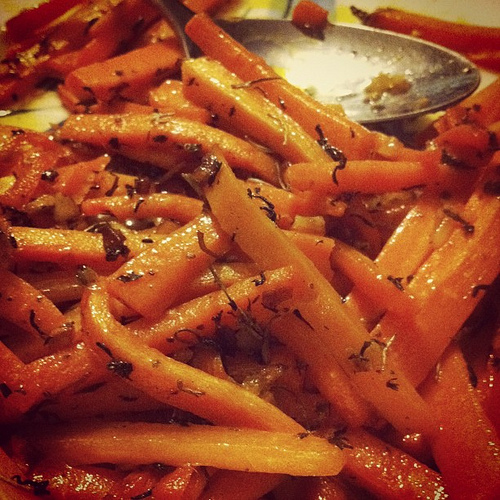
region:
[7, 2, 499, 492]
Cooked range vegetables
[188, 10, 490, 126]
Empty metal dish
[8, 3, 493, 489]
Oily cooked vegetables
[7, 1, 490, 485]
Vegetables cut in large pieces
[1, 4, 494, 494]
Vegetables covered with herbs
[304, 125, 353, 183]
Herb covering vegetables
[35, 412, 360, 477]
Rectangular vegetable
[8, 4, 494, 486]
Orange vegetables seasoned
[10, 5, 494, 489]
Vegetables with covered with some herbs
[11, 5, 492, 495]
Vegetables net to empty dish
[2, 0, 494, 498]
dish of sliced, buttered, herb carrots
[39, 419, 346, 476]
carrot with almost no herbs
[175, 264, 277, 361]
large pieces of herbs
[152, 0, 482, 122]
silver spoon for eating carrots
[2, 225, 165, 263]
horizontal sliced carrot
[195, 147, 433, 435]
sliced carrot laying diagonally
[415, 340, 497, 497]
almost vertical sliced carrot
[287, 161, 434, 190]
short and skinny sliced carrot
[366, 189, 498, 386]
long, fat sliced carrot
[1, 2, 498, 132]
plate showing through carrots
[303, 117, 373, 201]
cooking seasoning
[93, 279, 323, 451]
a yellow pasta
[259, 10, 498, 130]
a sliver spoon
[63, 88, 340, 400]
a bowl of pasta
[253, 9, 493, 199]
pasta on a spoon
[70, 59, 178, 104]
an orange carrot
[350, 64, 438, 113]
green seasoning on a spoon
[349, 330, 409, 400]
green seasoning on some pasta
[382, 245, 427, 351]
green seasoning on a carrot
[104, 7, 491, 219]
a spoon in a bowl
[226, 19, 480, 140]
Spoon with drops on it..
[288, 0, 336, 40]
Carrot, cut in cube.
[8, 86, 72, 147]
Yellow surface under plate.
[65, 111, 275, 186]
Carrot with leafy bits.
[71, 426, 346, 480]
Carrot with almost no leafy bits.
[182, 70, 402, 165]
Carrots side by side.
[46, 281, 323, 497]
Carrots forming vee.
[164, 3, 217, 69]
Silver spoon handle.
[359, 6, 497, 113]
Lone carrot near spoon.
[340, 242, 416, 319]
Very small cooked carrot.